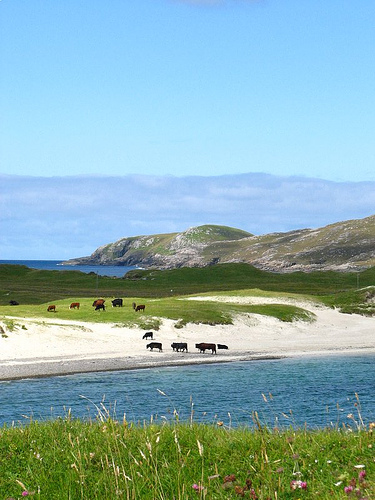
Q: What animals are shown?
A: Cows.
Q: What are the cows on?
A: Beach.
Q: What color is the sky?
A: Blue.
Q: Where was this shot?
A: Grassy field.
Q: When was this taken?
A: Daytime.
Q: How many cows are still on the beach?
A: 5.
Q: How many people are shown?
A: 0.